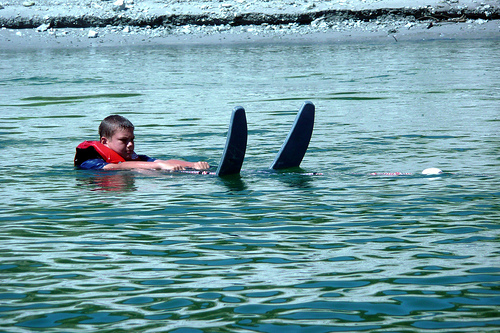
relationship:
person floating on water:
[74, 115, 177, 175] [220, 214, 291, 248]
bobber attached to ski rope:
[420, 164, 435, 181] [372, 168, 389, 181]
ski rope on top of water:
[372, 168, 389, 181] [220, 214, 291, 248]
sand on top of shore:
[64, 33, 98, 49] [245, 36, 287, 57]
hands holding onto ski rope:
[150, 160, 205, 175] [372, 168, 389, 181]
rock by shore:
[286, 23, 308, 36] [245, 36, 287, 57]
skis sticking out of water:
[219, 118, 294, 184] [220, 214, 291, 248]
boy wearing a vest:
[91, 120, 138, 172] [78, 146, 99, 171]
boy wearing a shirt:
[91, 120, 138, 172] [129, 158, 137, 162]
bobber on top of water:
[420, 164, 435, 181] [220, 214, 291, 248]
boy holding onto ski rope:
[91, 120, 138, 172] [372, 168, 389, 181]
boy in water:
[91, 120, 138, 172] [220, 214, 291, 248]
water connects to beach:
[220, 214, 291, 248] [173, 2, 217, 30]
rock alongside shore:
[286, 23, 308, 36] [245, 36, 287, 57]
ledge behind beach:
[166, 0, 228, 30] [173, 2, 217, 30]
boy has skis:
[91, 120, 138, 172] [219, 118, 294, 184]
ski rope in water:
[372, 168, 389, 181] [220, 214, 291, 248]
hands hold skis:
[150, 160, 205, 175] [219, 118, 294, 184]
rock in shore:
[286, 23, 308, 36] [245, 36, 287, 57]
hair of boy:
[102, 115, 122, 131] [91, 120, 138, 172]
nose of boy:
[125, 141, 132, 147] [91, 120, 138, 172]